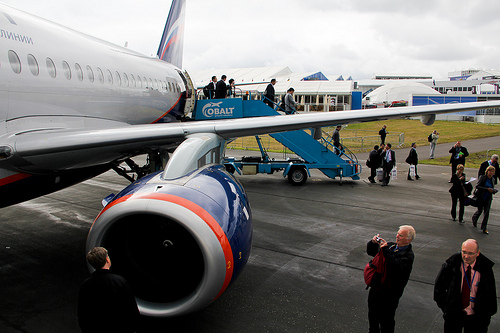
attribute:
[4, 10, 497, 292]
plane — royal navy blue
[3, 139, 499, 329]
runway — black, dark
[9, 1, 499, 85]
sky — gray, big, open, white, grey, red 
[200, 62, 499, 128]
buildings — short, tiny, small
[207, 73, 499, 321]
people — walking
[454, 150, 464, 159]
folder — neon green 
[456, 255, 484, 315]
shirt — pink 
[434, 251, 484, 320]
jacket — dark 